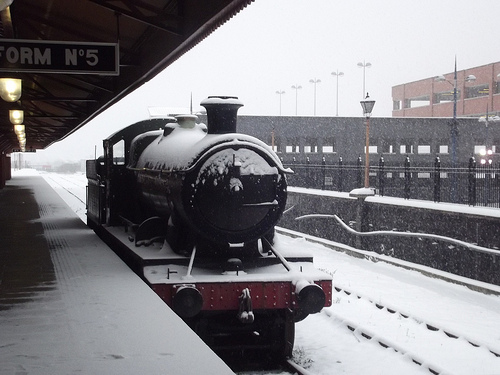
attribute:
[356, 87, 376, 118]
lamp — black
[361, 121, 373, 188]
post — metal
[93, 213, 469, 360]
tracks — snow-covered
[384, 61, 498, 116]
building — distant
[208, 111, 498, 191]
building — distant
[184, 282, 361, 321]
front — red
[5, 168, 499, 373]
snow — fresh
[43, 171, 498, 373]
train track — snow-covered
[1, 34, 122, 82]
hanging sign — black, white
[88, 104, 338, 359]
train — red, black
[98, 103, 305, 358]
train — black